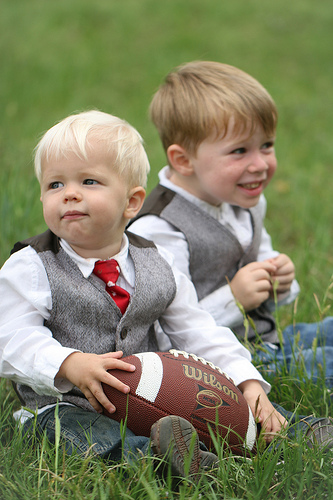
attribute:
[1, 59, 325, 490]
boys — sitting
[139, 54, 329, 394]
boy — smiling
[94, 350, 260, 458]
football — brown, white, Wilson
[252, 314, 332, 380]
blue jeans — pair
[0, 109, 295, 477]
boy — blond hair, blue eyes, holding, wearing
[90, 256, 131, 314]
tie — red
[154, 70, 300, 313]
boy — red hair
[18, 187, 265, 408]
vests — gray